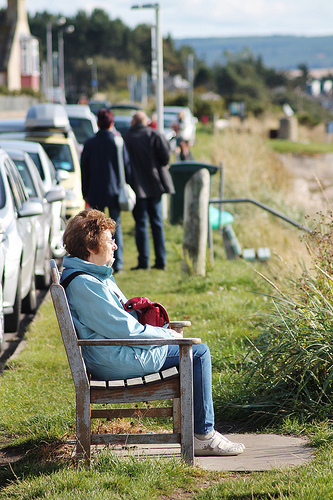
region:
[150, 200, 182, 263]
leg of a person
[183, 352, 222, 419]
leg of a person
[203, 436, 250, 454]
feet of a person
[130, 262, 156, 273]
feet of a person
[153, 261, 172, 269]
feet of a person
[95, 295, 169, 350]
arm of a person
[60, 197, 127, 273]
head of a person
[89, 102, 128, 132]
head of a person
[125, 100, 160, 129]
head of a person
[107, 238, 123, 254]
nose of a person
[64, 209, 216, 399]
woman sits on bench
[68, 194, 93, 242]
woman has brown hair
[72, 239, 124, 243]
woman is wearing glasses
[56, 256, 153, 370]
woman has blue coat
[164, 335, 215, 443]
woman has blue pants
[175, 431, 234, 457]
woman has white shoes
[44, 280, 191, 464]
bench is light grey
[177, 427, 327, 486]
grey concrete is underfoot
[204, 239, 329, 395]
green bush near woman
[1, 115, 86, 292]
line of cars behind woman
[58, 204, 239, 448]
this is a woman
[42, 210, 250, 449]
the woman is sitting on a bench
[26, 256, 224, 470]
this is a bench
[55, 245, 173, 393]
woman wearing blue jacket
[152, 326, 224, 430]
woman wearing blue jeans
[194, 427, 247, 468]
woman wearing white shoes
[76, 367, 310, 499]
cement under the bench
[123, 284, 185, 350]
woman holding a purse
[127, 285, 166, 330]
the purse is red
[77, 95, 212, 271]
people standing in background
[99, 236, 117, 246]
glasses on the woman's face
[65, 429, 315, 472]
small patch of gray cement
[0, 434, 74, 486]
bench shadow on the ground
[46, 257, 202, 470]
brown wooden bench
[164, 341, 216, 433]
blue jeans on the woman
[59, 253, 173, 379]
light blue jacket on the woman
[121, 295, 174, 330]
red bag in the woman's lap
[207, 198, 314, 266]
gray metal railing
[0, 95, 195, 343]
cars parked along the street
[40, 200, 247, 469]
An elderly lady sits and waits on a bench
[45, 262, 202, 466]
The bench is made of wood and old and in need of some paint.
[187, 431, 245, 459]
The old lady is wearing velcro-strapped white sneakers.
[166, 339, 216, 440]
The woman sitting on the bench is wearing long blue jean pants.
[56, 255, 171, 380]
The woman is wearing a warm long sleved blue shirt and a darker blue down vest.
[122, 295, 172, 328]
The woman is holding a red purse in her lap.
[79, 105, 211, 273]
There are a number of peopl standing a bit away in the distance from the lady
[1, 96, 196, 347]
A row of cars is parked along the curb behind where the older lady is sitting.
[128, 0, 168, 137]
A lamp post in facing the street in the distance behind the sitting lady.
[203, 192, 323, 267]
A round pipe type metal railing heads down the hill behind the seated old lady.